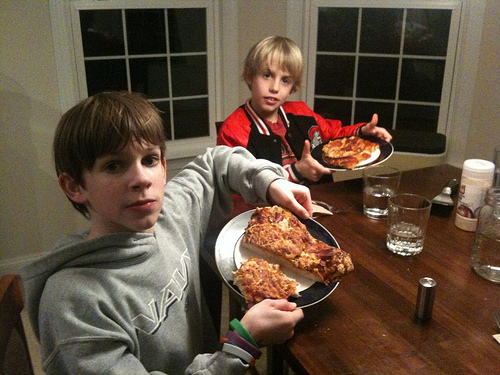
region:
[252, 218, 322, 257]
bread on the pizza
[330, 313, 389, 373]
the table is brown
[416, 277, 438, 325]
a can on the table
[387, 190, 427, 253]
a glass on the table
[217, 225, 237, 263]
reflection of light on the plate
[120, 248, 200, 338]
logo on the sweatshirt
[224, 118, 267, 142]
boy is wearing a black and red jacket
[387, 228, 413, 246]
clear liquid in the glass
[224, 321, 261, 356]
multi color bands on the arm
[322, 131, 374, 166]
pizza on the plate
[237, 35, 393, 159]
Boy holding slice of pizza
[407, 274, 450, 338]
Salt shaker on the table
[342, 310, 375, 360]
The table is made of wood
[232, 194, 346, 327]
Pizza on the plate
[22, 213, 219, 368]
Boy is wearing a sweatshirt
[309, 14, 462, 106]
Window in the background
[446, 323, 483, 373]
Light shining on table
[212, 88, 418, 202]
Boy is wearing a jacket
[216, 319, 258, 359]
Bracelets on the boys arm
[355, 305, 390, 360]
Marks on the table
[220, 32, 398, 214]
a boy with blond hair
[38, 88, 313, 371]
a boy with brown hair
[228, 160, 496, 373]
a brown wooden table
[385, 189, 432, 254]
a water glass on a table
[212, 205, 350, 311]
a round black and white plate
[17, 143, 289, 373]
a gray sweatshirt on a boy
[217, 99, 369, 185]
a red and black jacket on a boy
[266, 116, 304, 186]
a red shirt on a boy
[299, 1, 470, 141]
a window behind a boy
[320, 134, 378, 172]
pizza on a plate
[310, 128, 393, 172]
A black and white plate a blonde boy is holding.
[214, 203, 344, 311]
A black and white plate a boy in grey is holding.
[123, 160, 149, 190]
Nose on the face of a brown haired boy.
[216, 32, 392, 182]
A blonde boy in a red, white and black coat.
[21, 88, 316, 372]
Brown haired boy in a grey sweatshirt holding pizza.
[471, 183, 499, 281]
A clear mason jar with water in it.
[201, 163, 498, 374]
A brown kitchen table.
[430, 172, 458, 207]
A large spatula on the table near a white container.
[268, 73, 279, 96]
Nose on the blonde boys face.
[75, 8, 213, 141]
Eight visible window panes.